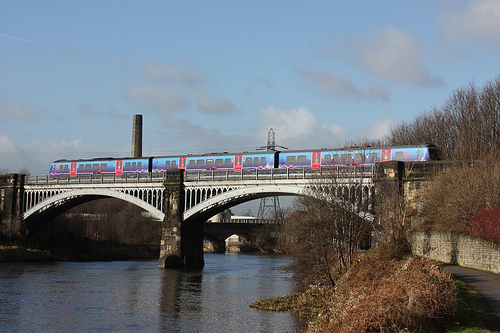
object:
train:
[47, 142, 442, 180]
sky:
[0, 0, 499, 174]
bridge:
[0, 160, 404, 270]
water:
[0, 248, 319, 333]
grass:
[249, 245, 498, 332]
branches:
[464, 205, 498, 242]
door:
[233, 155, 242, 173]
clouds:
[360, 81, 392, 104]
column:
[157, 169, 185, 269]